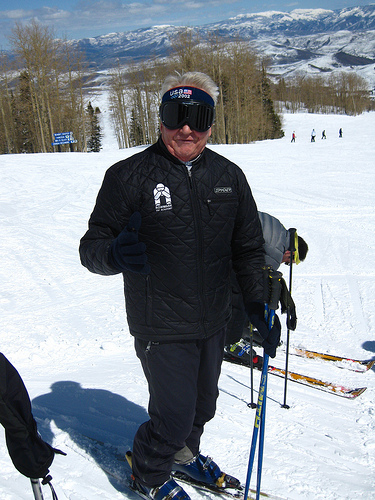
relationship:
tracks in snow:
[39, 382, 167, 498] [13, 258, 108, 382]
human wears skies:
[78, 70, 281, 500] [107, 442, 260, 499]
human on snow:
[78, 70, 281, 500] [0, 6, 372, 498]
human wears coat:
[78, 70, 281, 500] [79, 133, 266, 341]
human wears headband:
[78, 70, 281, 500] [157, 86, 219, 111]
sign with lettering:
[50, 130, 76, 145] [56, 134, 65, 142]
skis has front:
[223, 342, 375, 399] [332, 351, 373, 396]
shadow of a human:
[35, 369, 156, 493] [77, 73, 279, 498]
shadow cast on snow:
[31, 380, 155, 500] [1, 88, 374, 498]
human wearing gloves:
[78, 70, 281, 500] [113, 207, 282, 359]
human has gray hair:
[78, 70, 281, 500] [162, 68, 218, 96]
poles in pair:
[243, 265, 281, 499] [237, 263, 283, 498]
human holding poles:
[78, 70, 281, 500] [241, 269, 283, 497]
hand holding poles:
[250, 300, 282, 358] [241, 269, 283, 497]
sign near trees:
[51, 131, 78, 146] [0, 18, 285, 155]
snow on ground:
[1, 88, 374, 498] [2, 89, 374, 498]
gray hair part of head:
[160, 71, 220, 109] [157, 68, 219, 160]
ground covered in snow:
[6, 142, 281, 491] [0, 6, 372, 498]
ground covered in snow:
[7, 113, 328, 494] [71, 327, 100, 404]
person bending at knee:
[224, 209, 308, 362] [221, 276, 298, 387]